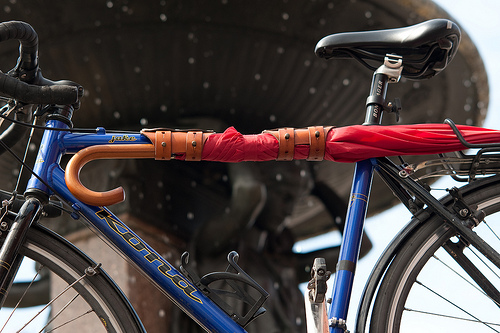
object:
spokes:
[397, 278, 499, 332]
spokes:
[38, 285, 85, 329]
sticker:
[85, 207, 211, 308]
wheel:
[352, 171, 499, 331]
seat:
[298, 13, 468, 83]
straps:
[185, 129, 205, 162]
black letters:
[181, 282, 204, 305]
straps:
[266, 127, 333, 161]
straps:
[151, 128, 174, 162]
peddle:
[311, 256, 333, 303]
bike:
[2, 17, 499, 330]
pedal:
[194, 230, 251, 292]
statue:
[200, 164, 375, 296]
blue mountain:
[14, 40, 280, 324]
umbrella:
[64, 117, 499, 207]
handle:
[63, 140, 158, 202]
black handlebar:
[0, 17, 83, 113]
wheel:
[4, 201, 151, 331]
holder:
[63, 143, 155, 207]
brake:
[445, 185, 484, 230]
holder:
[171, 245, 273, 325]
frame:
[21, 112, 489, 331]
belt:
[303, 127, 331, 163]